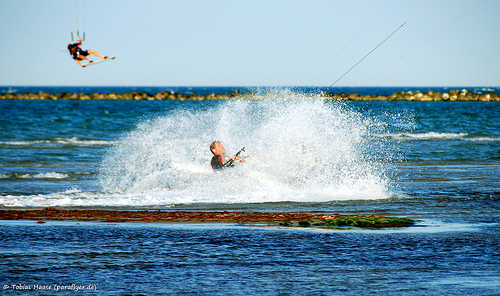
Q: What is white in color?
A: The water.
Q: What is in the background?
A: Many rocks.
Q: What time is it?
A: Afternoon.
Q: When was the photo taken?
A: During the daytime.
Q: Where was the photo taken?
A: In the water.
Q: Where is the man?
A: In the water.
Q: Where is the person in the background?
A: The air.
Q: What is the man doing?
A: Surfing.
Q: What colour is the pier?
A: Brown.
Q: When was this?
A: Daytime.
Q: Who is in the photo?
A: People.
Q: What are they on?
A: Water.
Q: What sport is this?
A: Surfing.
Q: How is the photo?
A: Clear.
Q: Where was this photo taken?
A: Ocean.